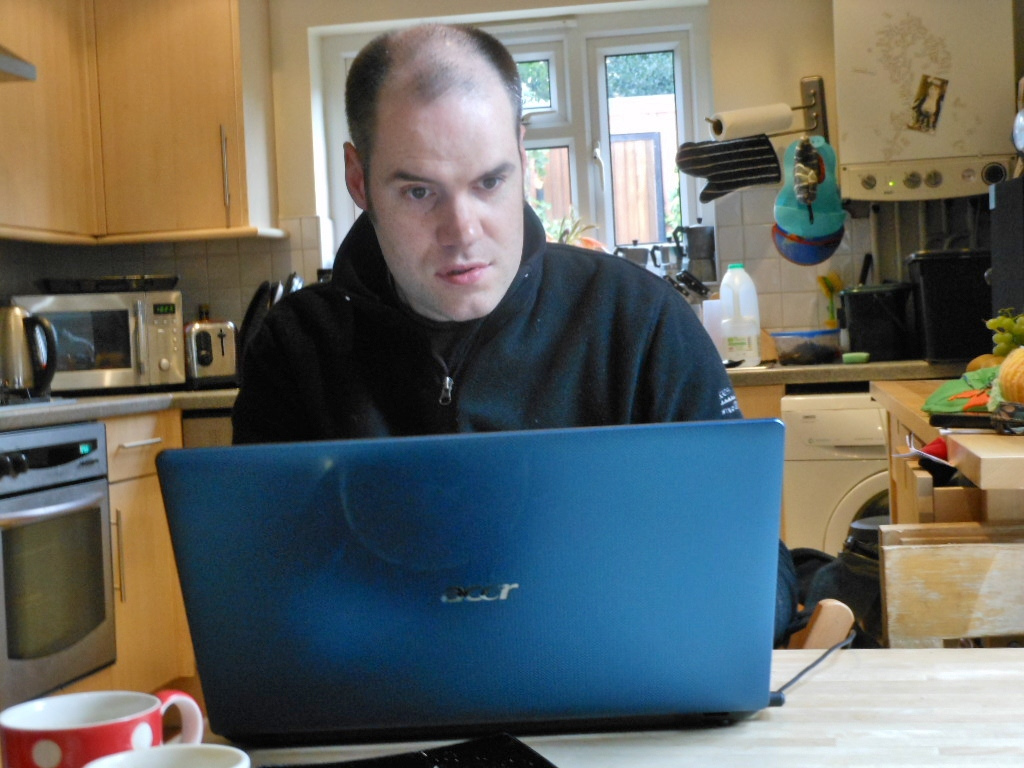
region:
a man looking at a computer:
[175, 30, 798, 719]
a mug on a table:
[10, 693, 187, 748]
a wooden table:
[159, 623, 1013, 760]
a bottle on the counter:
[712, 257, 766, 360]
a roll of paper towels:
[710, 99, 793, 135]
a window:
[601, 51, 672, 245]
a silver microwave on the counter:
[21, 285, 190, 385]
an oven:
[7, 413, 125, 682]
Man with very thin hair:
[160, 12, 876, 733]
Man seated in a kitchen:
[177, 23, 892, 688]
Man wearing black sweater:
[145, 25, 844, 696]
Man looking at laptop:
[147, 22, 860, 674]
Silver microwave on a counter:
[18, 274, 225, 398]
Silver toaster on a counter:
[170, 310, 248, 384]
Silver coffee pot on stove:
[2, 297, 73, 399]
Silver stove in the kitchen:
[2, 401, 158, 690]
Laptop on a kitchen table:
[129, 411, 857, 766]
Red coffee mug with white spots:
[10, 661, 216, 766]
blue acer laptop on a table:
[155, 411, 785, 754]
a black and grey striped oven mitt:
[671, 132, 785, 203]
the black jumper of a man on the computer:
[229, 211, 745, 446]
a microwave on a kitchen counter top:
[0, 282, 191, 401]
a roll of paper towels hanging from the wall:
[705, 101, 797, 139]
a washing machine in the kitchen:
[776, 395, 895, 573]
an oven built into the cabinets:
[2, 417, 119, 705]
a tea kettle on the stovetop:
[2, 300, 57, 405]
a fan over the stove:
[0, 53, 39, 88]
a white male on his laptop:
[125, 19, 803, 729]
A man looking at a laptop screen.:
[153, 11, 847, 762]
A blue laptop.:
[151, 408, 793, 763]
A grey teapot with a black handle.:
[4, 301, 53, 399]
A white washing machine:
[785, 390, 916, 559]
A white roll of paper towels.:
[706, 105, 798, 137]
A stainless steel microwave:
[21, 281, 192, 406]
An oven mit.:
[675, 130, 787, 208]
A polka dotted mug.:
[4, 673, 198, 763]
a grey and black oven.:
[2, 434, 121, 694]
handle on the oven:
[15, 499, 117, 534]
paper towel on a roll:
[691, 89, 827, 141]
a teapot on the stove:
[4, 285, 55, 418]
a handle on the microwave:
[119, 295, 162, 378]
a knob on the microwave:
[160, 351, 186, 394]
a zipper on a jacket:
[412, 322, 510, 427]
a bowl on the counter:
[780, 303, 860, 393]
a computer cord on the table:
[774, 623, 893, 713]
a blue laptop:
[156, 418, 785, 744]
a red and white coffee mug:
[0, 690, 207, 764]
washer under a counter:
[782, 391, 899, 556]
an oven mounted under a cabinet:
[0, 423, 119, 714]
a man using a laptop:
[225, 27, 798, 644]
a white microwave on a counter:
[10, 290, 188, 385]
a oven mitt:
[670, 138, 784, 203]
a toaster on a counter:
[183, 320, 240, 387]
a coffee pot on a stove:
[0, 308, 55, 397]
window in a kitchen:
[320, 26, 687, 298]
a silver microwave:
[13, 301, 188, 387]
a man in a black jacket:
[271, 98, 742, 472]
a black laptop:
[152, 445, 783, 720]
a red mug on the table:
[6, 705, 200, 753]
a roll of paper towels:
[713, 105, 799, 140]